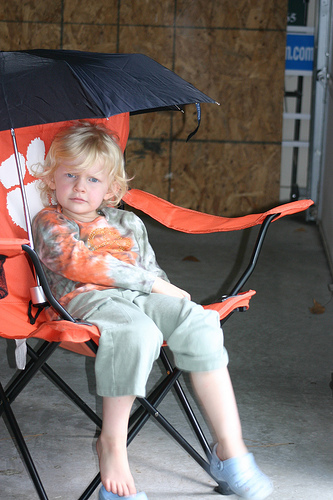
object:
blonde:
[36, 122, 132, 208]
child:
[32, 118, 275, 496]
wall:
[0, 0, 288, 217]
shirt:
[24, 203, 172, 322]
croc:
[208, 441, 274, 498]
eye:
[87, 177, 99, 185]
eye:
[62, 169, 76, 180]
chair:
[0, 111, 313, 498]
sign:
[285, 29, 314, 77]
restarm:
[122, 183, 315, 231]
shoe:
[211, 442, 274, 498]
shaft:
[8, 128, 48, 305]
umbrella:
[0, 50, 220, 309]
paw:
[0, 136, 58, 232]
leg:
[135, 396, 219, 487]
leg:
[0, 385, 51, 498]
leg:
[17, 336, 104, 425]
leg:
[7, 339, 60, 406]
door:
[321, 0, 332, 272]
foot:
[95, 426, 137, 496]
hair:
[37, 115, 133, 219]